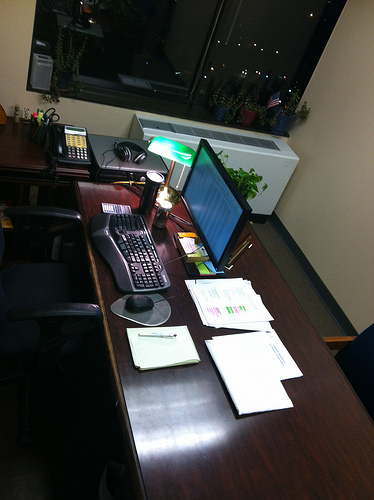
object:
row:
[208, 72, 311, 135]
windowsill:
[26, 100, 301, 135]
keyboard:
[90, 212, 170, 291]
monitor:
[179, 138, 253, 271]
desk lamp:
[156, 136, 196, 201]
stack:
[184, 277, 274, 333]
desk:
[84, 191, 359, 471]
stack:
[203, 330, 304, 417]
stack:
[125, 325, 201, 372]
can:
[152, 199, 174, 230]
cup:
[27, 119, 48, 146]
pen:
[36, 107, 41, 134]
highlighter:
[33, 110, 38, 119]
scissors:
[43, 108, 62, 125]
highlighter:
[37, 110, 45, 123]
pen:
[46, 117, 50, 134]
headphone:
[115, 140, 149, 164]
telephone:
[46, 122, 94, 174]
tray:
[173, 232, 226, 279]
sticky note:
[205, 260, 226, 276]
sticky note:
[195, 262, 208, 277]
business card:
[177, 238, 206, 261]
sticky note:
[178, 230, 199, 239]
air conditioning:
[127, 111, 306, 207]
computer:
[86, 132, 170, 175]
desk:
[1, 114, 98, 182]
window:
[26, 0, 347, 139]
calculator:
[101, 202, 133, 215]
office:
[1, 1, 374, 500]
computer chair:
[1, 204, 103, 408]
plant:
[49, 15, 91, 92]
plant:
[204, 76, 240, 122]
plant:
[235, 83, 269, 131]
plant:
[266, 88, 311, 135]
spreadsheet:
[203, 170, 229, 249]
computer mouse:
[125, 294, 154, 315]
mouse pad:
[109, 292, 173, 326]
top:
[134, 112, 296, 147]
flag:
[266, 89, 281, 112]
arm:
[2, 204, 81, 250]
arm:
[7, 303, 104, 356]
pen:
[138, 332, 179, 338]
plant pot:
[243, 109, 258, 125]